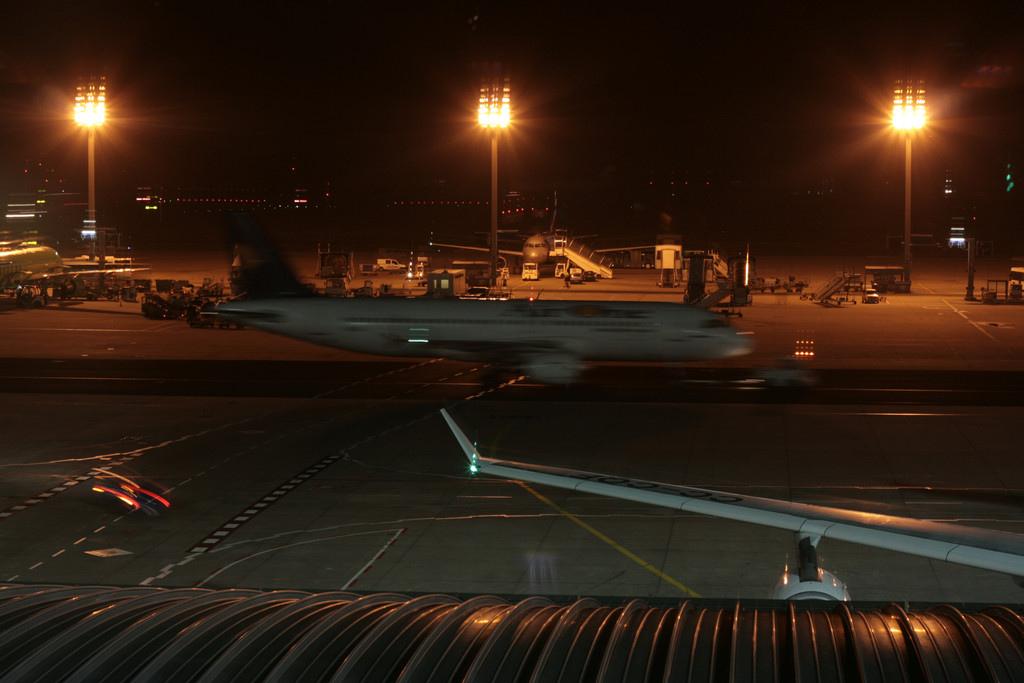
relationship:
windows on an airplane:
[264, 231, 789, 407] [205, 230, 793, 418]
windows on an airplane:
[283, 222, 748, 372] [255, 220, 781, 411]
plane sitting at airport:
[186, 273, 772, 431] [136, 139, 1012, 602]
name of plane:
[505, 296, 659, 335] [153, 195, 793, 476]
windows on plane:
[404, 301, 655, 340] [205, 225, 865, 437]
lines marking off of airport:
[131, 452, 294, 602] [37, 83, 977, 671]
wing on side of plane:
[402, 385, 1018, 619] [374, 376, 954, 675]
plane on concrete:
[183, 257, 762, 418] [153, 357, 532, 615]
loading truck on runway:
[26, 245, 147, 313] [19, 284, 248, 531]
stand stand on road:
[52, 463, 232, 563] [13, 459, 532, 630]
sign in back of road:
[935, 223, 983, 256] [810, 253, 1016, 409]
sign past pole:
[127, 186, 169, 225] [125, 190, 165, 264]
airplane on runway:
[183, 247, 789, 423] [132, 337, 949, 670]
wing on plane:
[402, 385, 1018, 619] [387, 374, 1018, 660]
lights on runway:
[47, 74, 138, 150] [37, 225, 575, 627]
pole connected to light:
[43, 83, 164, 172] [65, 124, 130, 267]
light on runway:
[464, 80, 510, 150] [326, 253, 642, 314]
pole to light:
[460, 80, 536, 150] [471, 145, 547, 303]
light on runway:
[872, 80, 955, 161] [801, 284, 1018, 513]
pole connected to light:
[872, 72, 939, 140] [883, 139, 946, 312]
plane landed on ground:
[462, 215, 705, 274] [90, 245, 987, 338]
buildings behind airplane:
[121, 171, 363, 221] [183, 214, 758, 397]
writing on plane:
[497, 301, 658, 327] [211, 201, 782, 387]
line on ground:
[477, 459, 733, 598] [19, 250, 1020, 603]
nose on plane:
[730, 333, 759, 364] [151, 217, 763, 390]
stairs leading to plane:
[558, 243, 621, 287] [487, 204, 561, 271]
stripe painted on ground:
[499, 445, 713, 593] [19, 250, 1020, 603]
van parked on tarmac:
[355, 251, 418, 280] [18, 253, 1021, 597]